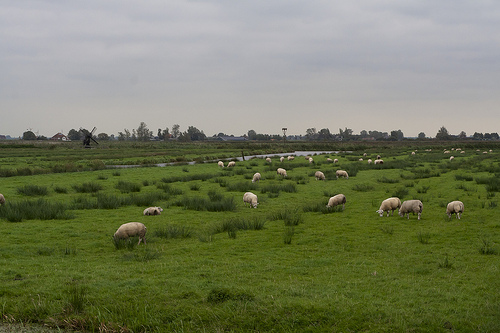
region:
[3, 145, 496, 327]
a bright green pasture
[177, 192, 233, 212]
tall grass in a pasture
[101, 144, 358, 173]
water running through a pasture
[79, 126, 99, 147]
a windmill in a field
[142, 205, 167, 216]
a sheep laying down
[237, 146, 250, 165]
a post next to water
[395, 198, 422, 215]
a grey sheep in a field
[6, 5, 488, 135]
a cloudy grey sky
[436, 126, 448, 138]
a tree on the horizon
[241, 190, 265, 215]
a sheep eating grass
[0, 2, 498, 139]
sky is gray and hazy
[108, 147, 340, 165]
water visible behind the field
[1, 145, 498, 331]
a field of green grass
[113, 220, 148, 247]
a sheep grazing in the field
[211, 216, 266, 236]
clumps of tall grass in the field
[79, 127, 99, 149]
a dark windmill in the distance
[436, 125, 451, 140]
some trees at the edge of the field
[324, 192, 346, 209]
sheep eating tall grass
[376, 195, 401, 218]
sheep standing next to sheep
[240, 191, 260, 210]
a white and woolly sheep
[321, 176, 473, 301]
the animals in field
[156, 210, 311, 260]
shrubs are in grass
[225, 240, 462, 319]
the grass is green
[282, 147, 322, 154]
the water is silver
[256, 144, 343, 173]
the water is between fields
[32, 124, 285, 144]
the trees in background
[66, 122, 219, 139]
the trees are green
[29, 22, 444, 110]
the sky is cloudy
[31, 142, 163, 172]
the crops are in field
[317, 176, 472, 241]
the animals are tan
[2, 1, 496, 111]
a sky filled with clouds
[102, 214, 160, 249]
a sheep grazing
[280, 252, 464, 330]
a field with green grass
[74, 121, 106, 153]
a brown wooden windmill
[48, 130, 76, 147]
a farmhouse with brown roof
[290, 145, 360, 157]
a stream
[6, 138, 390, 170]
a field with a clear stream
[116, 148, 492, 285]
a herd of sheep grazing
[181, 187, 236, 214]
a clump of tall green grass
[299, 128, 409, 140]
tree line with green leaves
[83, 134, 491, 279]
A bunch of sheep in a field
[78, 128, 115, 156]
There is a brown windmill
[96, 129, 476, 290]
A bunch of sheep grazing on grass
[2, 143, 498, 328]
The grass is very green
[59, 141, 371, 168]
There is a stream running through the property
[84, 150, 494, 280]
The sheep are white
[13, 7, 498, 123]
There are clouds in the sky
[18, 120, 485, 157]
There are trees in the background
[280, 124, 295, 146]
There is a tower in the background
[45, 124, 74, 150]
There is a house behind the windmill